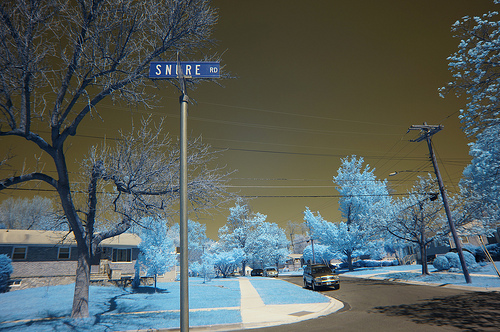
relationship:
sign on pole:
[151, 48, 242, 96] [166, 95, 212, 328]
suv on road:
[300, 267, 368, 304] [353, 284, 427, 326]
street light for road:
[391, 161, 419, 191] [353, 284, 427, 326]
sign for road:
[151, 48, 242, 96] [353, 284, 427, 326]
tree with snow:
[343, 163, 383, 209] [373, 202, 374, 204]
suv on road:
[300, 267, 349, 292] [353, 284, 427, 326]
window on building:
[52, 243, 78, 265] [0, 218, 173, 311]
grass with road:
[191, 284, 252, 324] [353, 284, 427, 326]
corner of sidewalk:
[236, 293, 300, 329] [232, 272, 266, 331]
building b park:
[0, 218, 173, 311] [332, 187, 461, 325]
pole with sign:
[166, 95, 212, 328] [151, 48, 242, 96]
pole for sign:
[166, 95, 212, 328] [151, 48, 242, 96]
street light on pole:
[391, 161, 419, 191] [166, 95, 212, 328]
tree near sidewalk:
[343, 163, 383, 209] [232, 272, 266, 331]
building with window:
[0, 218, 173, 311] [52, 243, 78, 265]